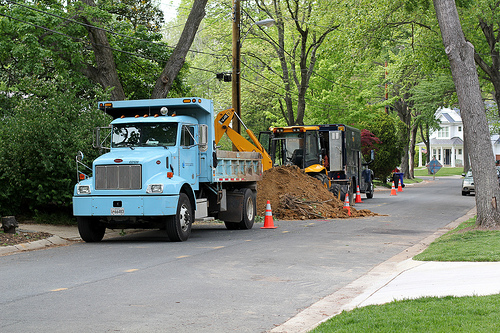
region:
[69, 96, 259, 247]
Blue dump truck on street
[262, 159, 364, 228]
Pile of red dirt on street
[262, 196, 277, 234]
orange and white traffic cone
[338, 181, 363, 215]
two orange and white traffic cones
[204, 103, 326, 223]
yellow road machine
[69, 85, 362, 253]
Truck unloaded pile of dirt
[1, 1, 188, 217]
Large green trees behind truck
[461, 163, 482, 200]
Car parked on street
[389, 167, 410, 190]
man leaning over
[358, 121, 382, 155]
Red tree in distance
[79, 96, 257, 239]
a light blue dump truck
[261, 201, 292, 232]
an orange cone in the street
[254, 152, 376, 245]
a large pile of dirt in the street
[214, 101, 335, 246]
an orange backhoe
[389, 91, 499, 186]
a large white two story house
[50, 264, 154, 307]
yellow lines in the street to divide the lanes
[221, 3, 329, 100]
power lines run parallel to the street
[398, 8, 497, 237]
trees line the street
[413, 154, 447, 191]
a sign at the end of the street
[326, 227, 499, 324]
green grass lining the driveway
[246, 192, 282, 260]
orange and white traffic cone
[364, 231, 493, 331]
green grass on each side of driveway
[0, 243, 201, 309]
yellow painted line on road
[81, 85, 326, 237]
a large white dump truck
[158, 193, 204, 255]
black tire with silver rim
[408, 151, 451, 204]
small sign for construction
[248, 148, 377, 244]
large pile of dirt and rock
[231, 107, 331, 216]
a yellow and black earth mover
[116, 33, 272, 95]
telephone pole with wires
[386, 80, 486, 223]
large white house at end of street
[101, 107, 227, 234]
Blue dump truck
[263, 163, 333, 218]
Pile of dirt on the road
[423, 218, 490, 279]
Patch of grass on sidewalk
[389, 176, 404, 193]
Orange and white street cones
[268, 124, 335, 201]
Yellow Pay Loader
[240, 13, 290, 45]
White street lamp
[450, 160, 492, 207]
Car parked on the street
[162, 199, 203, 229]
Chrome wheel on a dump truck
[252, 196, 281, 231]
Traffic cone next to dump truck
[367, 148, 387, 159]
Mirror on a work truck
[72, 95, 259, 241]
a blue dump truck parked in the street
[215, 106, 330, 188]
a yellow back hoe digging up the street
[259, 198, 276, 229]
an orange safety cone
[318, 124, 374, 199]
a utility truck parked behind the back hoe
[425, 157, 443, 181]
a men working sign at the intersection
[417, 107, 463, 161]
a white house at the end of the street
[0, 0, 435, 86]
trees lining the side of the street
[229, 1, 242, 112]
a telephone pole on the curb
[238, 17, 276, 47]
a street light over the street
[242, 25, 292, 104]
telephone lines extending across the street